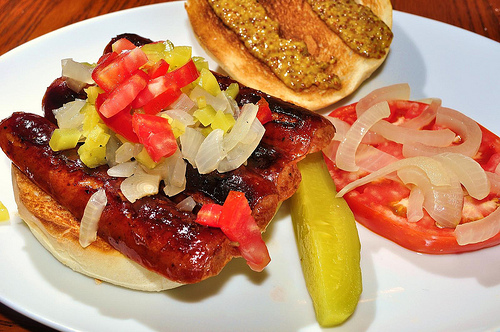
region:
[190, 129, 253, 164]
white diced onions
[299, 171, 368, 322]
a thinly sliced gree pickle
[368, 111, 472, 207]
onions pieces on top of a tomato slice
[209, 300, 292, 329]
a white plate with a meal on it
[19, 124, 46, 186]
sausage link on a tortilla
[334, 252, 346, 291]
tiny seeds on the pickle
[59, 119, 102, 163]
diced green peppers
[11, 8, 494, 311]
a delicious lunch on a plate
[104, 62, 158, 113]
tomato chunks on top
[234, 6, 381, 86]
bread with a special sauce on top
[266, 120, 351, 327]
a pickle on a plate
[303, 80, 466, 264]
a slice of tomato with onions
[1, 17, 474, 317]
a plate of food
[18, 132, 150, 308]
a piece of bread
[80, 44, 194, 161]
chopped tomatoes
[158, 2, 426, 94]
sauce on a bread bun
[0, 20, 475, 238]
a white plate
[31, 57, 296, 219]
different toppings for a sandwich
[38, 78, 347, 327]
half of a sandwich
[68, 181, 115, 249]
a piece of onion on a sandwich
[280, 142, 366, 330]
a green pickle wedge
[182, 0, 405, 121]
a bread bun top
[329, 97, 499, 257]
a round slice of tomato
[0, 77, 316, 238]
sliced pieces of sausage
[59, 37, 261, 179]
chopped vegetables piled on top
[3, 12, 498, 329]
a round white dinner plate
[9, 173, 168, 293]
a bottom piece of the bun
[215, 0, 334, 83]
a spread on the top bun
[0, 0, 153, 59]
a brown wooden table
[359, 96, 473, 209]
sliced onions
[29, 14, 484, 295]
sandwich on a plate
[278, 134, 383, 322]
dill pickle wedge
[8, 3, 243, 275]
food on a round white plate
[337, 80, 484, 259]
slice of red tomato with white slices onions on top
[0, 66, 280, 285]
square grilled meat on the bottom of a sandwich roll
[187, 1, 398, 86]
top half of sandwich roll has mustard on it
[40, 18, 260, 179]
vegetable topping on the grilled meat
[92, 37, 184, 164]
pieces of red tomato on the sandwich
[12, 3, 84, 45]
white dish on brown wood grain table top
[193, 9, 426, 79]
two strips of stone ground mustard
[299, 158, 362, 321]
The pickle on the white dish.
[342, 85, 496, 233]
The onions on top of the tomato.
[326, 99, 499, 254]
The tomato under the sliced onions.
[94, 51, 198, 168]
Chopped up tomatoes on the sausage.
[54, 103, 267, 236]
Chopped up onions on the sausages.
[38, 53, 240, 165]
Yellow peppers cut up on the sausages.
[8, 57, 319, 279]
The sausages on the bun.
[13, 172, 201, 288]
The toasted bun holding the sausages.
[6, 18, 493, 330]
The white dish the food is on.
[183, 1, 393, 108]
Top piece of the toasted bun.